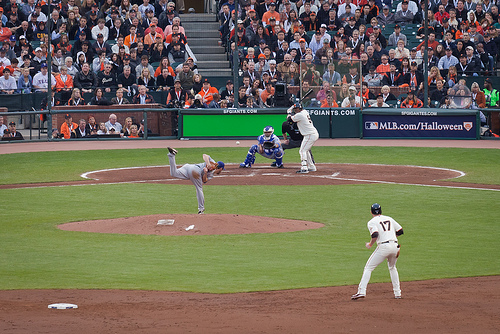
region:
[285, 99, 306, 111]
batter wears black helmet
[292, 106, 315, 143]
batter wears white shirt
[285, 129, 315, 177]
batter wears white pants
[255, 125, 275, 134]
catcher wears blue helmet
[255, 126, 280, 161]
catcher wears blue chest guard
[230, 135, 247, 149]
baseball is white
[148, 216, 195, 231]
rosin bag behind pitcher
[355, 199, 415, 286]
player takes lead off second base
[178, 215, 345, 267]
infield grass is green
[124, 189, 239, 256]
infield dirt is tan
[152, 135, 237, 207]
The pitcher pitches the ball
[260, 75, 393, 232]
The batter gets ready to hit the ball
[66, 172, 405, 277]
The pitching mound covered in dust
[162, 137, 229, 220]
The pitcher has dirty pants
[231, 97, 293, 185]
The catcher is wearing equipment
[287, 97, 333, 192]
The batter is wearing a white uniform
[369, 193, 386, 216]
The runner is wearing a helmet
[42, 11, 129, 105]
The crowd is watching the game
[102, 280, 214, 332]
The field has dirt around the bases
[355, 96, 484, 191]
This is a Major League game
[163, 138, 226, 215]
baseball player with leg bent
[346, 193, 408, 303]
baseball player wearing white uniform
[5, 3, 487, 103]
crowd of people at stadium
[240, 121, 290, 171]
baseball catcher crouched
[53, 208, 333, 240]
dirt pitcher's mound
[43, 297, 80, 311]
white baseball base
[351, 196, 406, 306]
baseball player wearing blue helmet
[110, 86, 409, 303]
baseball game in progress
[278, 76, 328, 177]
baseball player raising bat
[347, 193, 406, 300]
baseball uniform with number 17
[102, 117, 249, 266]
pitcher pitching the ball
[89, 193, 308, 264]
pitcher's mound with bag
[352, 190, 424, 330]
player standing on field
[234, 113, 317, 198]
catcher kneeling behind home plate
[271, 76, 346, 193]
batter ready to swing bat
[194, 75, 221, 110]
person wearing orange shirt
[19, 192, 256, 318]
second base bag behind pitcher's mound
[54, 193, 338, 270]
green grass surrounding pitcher's mound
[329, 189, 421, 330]
player wearing white uniform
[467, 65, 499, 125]
person wearing green shirt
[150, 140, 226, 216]
a man throwing a baseball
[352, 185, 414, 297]
a man with the number 17 on his uniform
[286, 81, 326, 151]
a man holding a bat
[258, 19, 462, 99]
several people sitting in bleachers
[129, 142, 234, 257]
a man standing on the pitchers mound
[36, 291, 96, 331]
a white pad on a baseball field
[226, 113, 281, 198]
a man wearing a catchers mitt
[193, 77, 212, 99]
a man wearing a cap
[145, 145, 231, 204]
a man with one foot raised off the ground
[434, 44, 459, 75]
a man wearing a blue shirt